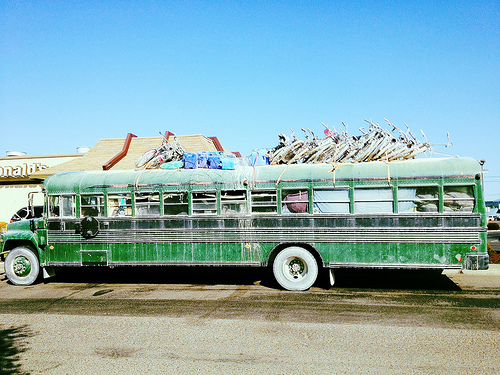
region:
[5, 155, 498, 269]
very old green bus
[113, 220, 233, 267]
worn green paint on the bus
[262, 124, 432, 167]
row of bikes on the bus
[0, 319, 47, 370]
shadow cast by a tree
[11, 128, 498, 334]
green bus parked on the road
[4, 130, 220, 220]
the top of a mcdonalds building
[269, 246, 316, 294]
old bus tire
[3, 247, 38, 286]
tire with a green rim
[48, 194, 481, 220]
row of bus windows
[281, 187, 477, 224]
items inside the bus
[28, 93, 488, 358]
a bus on the road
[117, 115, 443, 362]
a bus on the street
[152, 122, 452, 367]
an old bus on the road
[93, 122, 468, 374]
a old bus on the street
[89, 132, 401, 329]
a green bus on the road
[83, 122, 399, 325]
a green bus that is street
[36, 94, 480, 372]
an old green bus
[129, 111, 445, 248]
bikes on top of a bus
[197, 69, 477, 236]
bikes on top of an old bus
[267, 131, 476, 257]
a bike on the green bus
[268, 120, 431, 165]
row of bicycles on the roof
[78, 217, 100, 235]
the street sign is closed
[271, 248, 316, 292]
the tire is white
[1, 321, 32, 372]
shadow on the ground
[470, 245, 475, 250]
red reflective light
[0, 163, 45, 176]
letters on the building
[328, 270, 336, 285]
white mud flap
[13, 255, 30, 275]
the rim is green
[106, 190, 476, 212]
inside the bus is full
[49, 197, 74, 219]
bus driver window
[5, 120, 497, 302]
an old green bus with bicycles on top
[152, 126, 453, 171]
several bicycles stacked on a bus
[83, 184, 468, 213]
the passenger windows of a bus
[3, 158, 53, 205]
a McDonald's restaurant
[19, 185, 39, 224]
the side window of a bus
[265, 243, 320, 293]
a wheel on a bus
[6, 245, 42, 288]
a wheel on a bus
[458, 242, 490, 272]
the back bumper on a bus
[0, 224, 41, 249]
the front fender on a bus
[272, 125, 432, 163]
several bicycles lying on the side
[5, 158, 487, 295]
A very dirty green school bus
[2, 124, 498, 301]
A dirty green school bus with dozens of bikes on the roof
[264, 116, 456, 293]
Dozens of bikes atop a green school bus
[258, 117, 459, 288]
Several bicycles being transported atop a green school bus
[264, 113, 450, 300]
Several bicycles being transported atop a green bus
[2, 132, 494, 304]
A green bus parked outside a McDonald's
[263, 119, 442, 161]
Several bikes stacked closeley beside each other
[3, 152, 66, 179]
Last half of a McDonalds sign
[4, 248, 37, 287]
Partially deflated work tire with green center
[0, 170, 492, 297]
A delapidated green bus